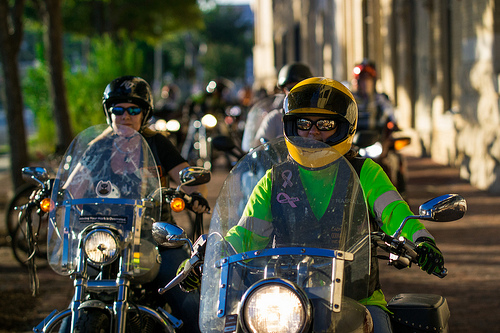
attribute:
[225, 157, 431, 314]
shirt — yellow, green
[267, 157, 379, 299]
vest — black, woman's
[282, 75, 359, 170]
helmet — yellow, black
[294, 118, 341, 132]
sunglasses — polarized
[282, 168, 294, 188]
ribbon — pink, awareness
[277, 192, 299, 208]
ribbon — pink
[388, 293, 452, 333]
saddlebag — black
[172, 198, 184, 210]
light — yellow, turn signal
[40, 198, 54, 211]
light — yellow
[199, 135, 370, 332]
windshield — bug splattered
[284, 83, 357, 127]
visor — up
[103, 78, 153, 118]
helmet — black, white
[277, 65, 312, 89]
helmet — black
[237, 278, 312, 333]
headlight — motorcycle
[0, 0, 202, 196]
tree — green, blurry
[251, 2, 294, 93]
building — out of focus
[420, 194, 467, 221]
mirror — rear view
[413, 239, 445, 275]
glove — green, black, on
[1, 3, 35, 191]
trunk — brown